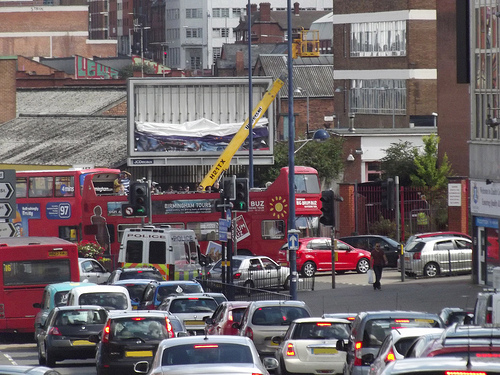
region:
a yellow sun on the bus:
[267, 191, 293, 222]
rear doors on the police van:
[121, 234, 169, 276]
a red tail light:
[283, 341, 295, 361]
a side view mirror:
[134, 354, 151, 374]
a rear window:
[159, 333, 256, 373]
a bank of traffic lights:
[316, 187, 341, 232]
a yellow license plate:
[308, 342, 340, 361]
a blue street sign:
[283, 229, 302, 251]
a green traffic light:
[233, 200, 246, 210]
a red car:
[273, 234, 375, 282]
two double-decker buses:
[15, 164, 329, 274]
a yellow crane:
[206, 23, 327, 191]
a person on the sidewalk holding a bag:
[365, 238, 392, 295]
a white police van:
[113, 220, 204, 288]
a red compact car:
[279, 229, 375, 281]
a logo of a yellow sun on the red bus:
[266, 192, 292, 223]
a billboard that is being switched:
[125, 72, 277, 163]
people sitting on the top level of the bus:
[153, 181, 229, 206]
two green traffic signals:
[121, 174, 256, 219]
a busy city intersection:
[12, 95, 492, 365]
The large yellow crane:
[195, 28, 322, 189]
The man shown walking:
[363, 241, 393, 295]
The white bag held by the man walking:
[363, 267, 378, 286]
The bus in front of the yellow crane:
[80, 163, 322, 265]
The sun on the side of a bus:
[267, 194, 290, 219]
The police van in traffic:
[113, 221, 204, 281]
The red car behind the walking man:
[273, 235, 375, 277]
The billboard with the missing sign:
[125, 73, 277, 165]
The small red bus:
[0, 233, 83, 336]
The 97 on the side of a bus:
[58, 202, 73, 217]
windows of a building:
[347, 18, 408, 58]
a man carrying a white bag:
[367, 242, 389, 291]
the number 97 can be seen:
[56, 201, 68, 216]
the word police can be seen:
[125, 230, 165, 236]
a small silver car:
[205, 250, 300, 292]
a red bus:
[0, 235, 80, 341]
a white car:
[275, 313, 351, 373]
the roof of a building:
[0, 111, 126, 167]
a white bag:
[364, 267, 376, 286]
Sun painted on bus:
[266, 193, 296, 223]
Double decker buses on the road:
[2, 157, 329, 261]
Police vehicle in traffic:
[115, 220, 206, 296]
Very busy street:
[6, 157, 483, 373]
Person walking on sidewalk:
[363, 237, 400, 292]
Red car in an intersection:
[273, 231, 373, 280]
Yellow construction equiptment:
[184, 20, 334, 195]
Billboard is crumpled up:
[132, 82, 275, 159]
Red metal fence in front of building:
[349, 173, 459, 248]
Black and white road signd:
[0, 167, 20, 237]